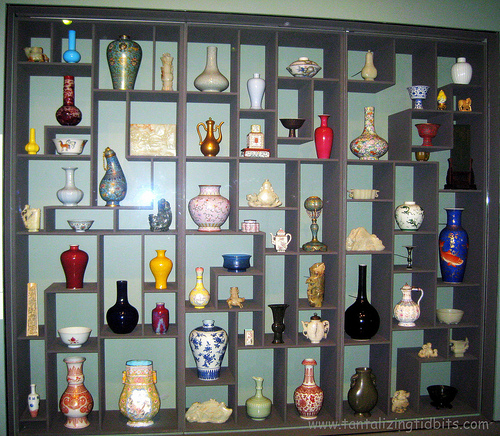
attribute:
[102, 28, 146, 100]
pottery — in photo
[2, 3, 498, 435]
cabinet — in photo, glass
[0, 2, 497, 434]
wall — in back, white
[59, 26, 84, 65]
vase — blue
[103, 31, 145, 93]
vase — green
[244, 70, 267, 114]
vase — white, on shelf, decorative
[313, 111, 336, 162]
vase — red, on shelf, one of many, available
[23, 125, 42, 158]
vase — yellow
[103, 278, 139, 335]
vase — black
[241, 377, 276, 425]
vase — green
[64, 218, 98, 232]
bowl — white, blue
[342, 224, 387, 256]
vase — seashell looking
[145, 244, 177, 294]
vase — shiny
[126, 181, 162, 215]
light — shining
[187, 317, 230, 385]
vase — blue, white, with birds on it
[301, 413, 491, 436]
text — white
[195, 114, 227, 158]
teapot — small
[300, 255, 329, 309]
vase — grown, brown